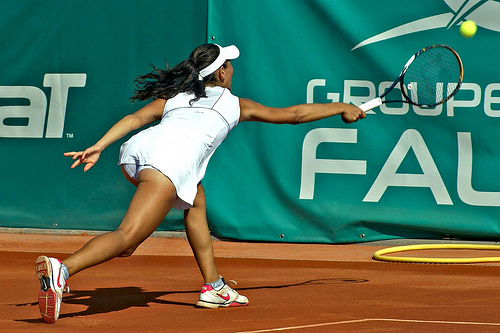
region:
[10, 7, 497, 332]
tennis player hitting a ball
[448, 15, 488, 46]
a ball in the air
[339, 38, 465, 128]
a black and white racket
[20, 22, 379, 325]
tennis player is bend forward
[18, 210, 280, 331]
shadow of a tennis player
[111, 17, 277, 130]
tennis player combs in a pony tail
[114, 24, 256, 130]
tennis player has black hair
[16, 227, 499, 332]
floor of tennis court is brown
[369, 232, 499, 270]
a yellow circle on ground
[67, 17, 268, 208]
tennis player wears a white dress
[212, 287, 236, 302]
Nike symbol on shoe.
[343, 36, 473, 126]
Black tennis racket.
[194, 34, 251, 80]
Sun visor.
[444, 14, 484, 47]
Tennis ball about to be hit.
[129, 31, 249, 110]
Woman's hair in a pony tail.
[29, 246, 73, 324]
red and white tennis shoe.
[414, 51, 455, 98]
W on tennis racket.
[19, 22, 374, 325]
Woman reaching out to hit a tennis ball with her racket.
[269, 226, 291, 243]
Metal in ad banner.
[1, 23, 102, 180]
White lettering on green background.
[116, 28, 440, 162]
A woman playing tennis.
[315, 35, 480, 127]
A tennis racquet with a white handle.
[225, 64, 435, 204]
A green sign with white lettering.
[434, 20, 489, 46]
A green tennis ball.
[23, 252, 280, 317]
White and pink tennis shoes.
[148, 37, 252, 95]
A woman wearing a visor.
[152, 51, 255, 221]
A woman dressed in a white tennis outfit.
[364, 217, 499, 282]
A yellow hose on the ground.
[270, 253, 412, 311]
A rust colored tennis court.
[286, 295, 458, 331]
A white line drawn on a tennis court.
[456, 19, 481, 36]
A Small tennis ball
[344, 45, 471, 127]
A white handle tennis racket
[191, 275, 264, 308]
Comftable nike white sport shoe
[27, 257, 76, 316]
Comftable nike white sport shoe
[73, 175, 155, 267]
Fine, smooth feet of player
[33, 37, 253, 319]
The Official tennis outfit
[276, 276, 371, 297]
The shadow of tennis racket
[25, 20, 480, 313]
A woman playing tennis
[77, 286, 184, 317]
A woman's shadow playing tennis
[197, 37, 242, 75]
A white tennis cup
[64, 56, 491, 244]
picture taken outdoors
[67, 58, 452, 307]
picture taken during the day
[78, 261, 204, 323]
the shadow of the player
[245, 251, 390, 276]
the court is brown in color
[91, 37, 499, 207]
a tennis player is playing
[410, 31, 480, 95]
a ball is in the air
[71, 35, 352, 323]
the player is stretched out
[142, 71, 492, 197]
the woman holds a racket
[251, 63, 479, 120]
the racket is in her right arm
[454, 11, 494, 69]
the tennis ball is yellow